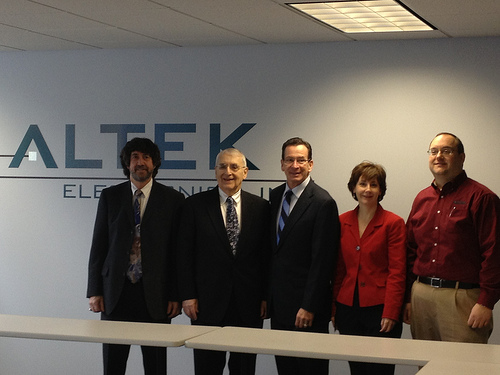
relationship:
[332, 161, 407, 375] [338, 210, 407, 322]
lady in jacket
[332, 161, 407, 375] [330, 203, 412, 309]
lady wearing a jacket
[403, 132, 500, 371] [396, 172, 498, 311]
man wearing shirt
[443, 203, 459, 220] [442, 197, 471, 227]
pen in pocket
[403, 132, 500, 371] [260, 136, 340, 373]
man wearing man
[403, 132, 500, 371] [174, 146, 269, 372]
man wearing man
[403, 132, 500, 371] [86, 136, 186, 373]
man wearing man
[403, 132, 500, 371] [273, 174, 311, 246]
man wearing shirt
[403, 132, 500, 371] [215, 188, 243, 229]
man wearing shirt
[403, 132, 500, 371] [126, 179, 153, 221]
man wearing shirt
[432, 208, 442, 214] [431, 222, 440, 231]
button on button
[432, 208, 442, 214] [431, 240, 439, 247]
button on button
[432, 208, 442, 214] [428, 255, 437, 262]
button on button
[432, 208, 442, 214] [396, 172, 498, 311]
button on shirt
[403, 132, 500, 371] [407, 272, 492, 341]
man wearing pants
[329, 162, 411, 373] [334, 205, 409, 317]
lady has on a jacket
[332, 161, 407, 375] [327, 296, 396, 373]
lady wearing pants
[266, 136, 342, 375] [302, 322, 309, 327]
man wearing ring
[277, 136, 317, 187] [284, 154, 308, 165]
man wearing glasses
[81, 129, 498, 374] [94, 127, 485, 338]
people standing in line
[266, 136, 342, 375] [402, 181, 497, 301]
man wearing shirt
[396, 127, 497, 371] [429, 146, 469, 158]
man wearing glasses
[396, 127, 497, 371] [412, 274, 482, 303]
man wearing belt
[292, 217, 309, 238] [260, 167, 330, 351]
pocket in jacket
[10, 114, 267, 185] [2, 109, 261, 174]
letters on wall